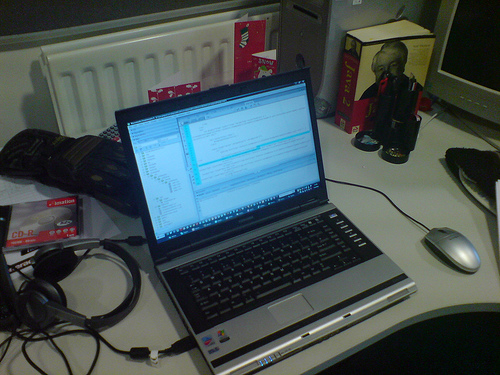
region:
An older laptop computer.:
[115, 66, 418, 374]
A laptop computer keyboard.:
[176, 212, 362, 322]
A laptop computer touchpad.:
[265, 292, 314, 328]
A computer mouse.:
[325, 143, 482, 275]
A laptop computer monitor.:
[120, 76, 322, 246]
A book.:
[332, 18, 435, 133]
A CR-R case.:
[0, 183, 82, 253]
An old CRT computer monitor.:
[423, 2, 498, 126]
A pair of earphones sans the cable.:
[14, 237, 141, 334]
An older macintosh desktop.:
[275, 0, 445, 118]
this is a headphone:
[46, 242, 141, 329]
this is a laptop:
[170, 109, 335, 309]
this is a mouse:
[426, 227, 478, 267]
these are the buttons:
[220, 255, 285, 277]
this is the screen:
[158, 112, 280, 182]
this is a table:
[408, 161, 444, 198]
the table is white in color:
[407, 163, 440, 198]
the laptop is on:
[133, 103, 299, 194]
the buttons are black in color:
[233, 254, 298, 283]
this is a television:
[447, 1, 499, 78]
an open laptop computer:
[112, 65, 418, 374]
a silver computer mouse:
[423, 225, 478, 275]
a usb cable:
[77, 325, 197, 367]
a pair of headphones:
[16, 234, 146, 330]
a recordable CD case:
[0, 192, 80, 250]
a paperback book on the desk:
[334, 15, 436, 135]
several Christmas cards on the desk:
[147, 13, 277, 102]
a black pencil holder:
[353, 73, 420, 162]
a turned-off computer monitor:
[428, 1, 499, 122]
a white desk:
[0, 99, 499, 374]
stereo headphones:
[24, 230, 146, 347]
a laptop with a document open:
[122, 87, 427, 331]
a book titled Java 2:
[332, 23, 439, 133]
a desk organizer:
[354, 71, 430, 165]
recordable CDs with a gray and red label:
[6, 192, 84, 254]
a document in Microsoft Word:
[185, 93, 317, 199]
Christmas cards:
[235, 20, 279, 81]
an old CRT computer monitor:
[437, 3, 494, 138]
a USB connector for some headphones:
[149, 324, 209, 361]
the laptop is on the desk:
[79, 73, 459, 343]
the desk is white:
[360, 159, 490, 247]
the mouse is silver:
[419, 205, 490, 287]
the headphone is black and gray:
[6, 235, 173, 364]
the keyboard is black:
[156, 238, 409, 316]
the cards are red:
[228, 12, 325, 130]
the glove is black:
[3, 121, 166, 221]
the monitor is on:
[120, 105, 368, 242]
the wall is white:
[13, 57, 57, 122]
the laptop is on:
[93, 91, 412, 365]